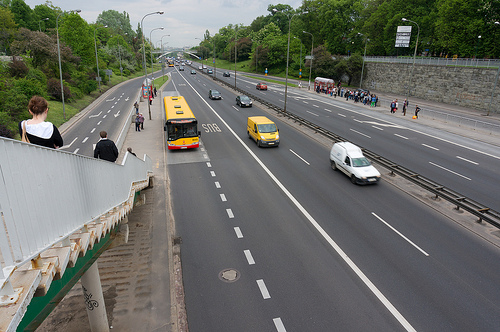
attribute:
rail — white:
[0, 134, 147, 169]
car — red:
[254, 79, 270, 91]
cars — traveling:
[135, 97, 397, 201]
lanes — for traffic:
[155, 80, 410, 319]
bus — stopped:
[158, 89, 202, 154]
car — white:
[315, 136, 382, 192]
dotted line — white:
[202, 173, 291, 330]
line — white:
[169, 60, 419, 330]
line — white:
[365, 207, 426, 255]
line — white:
[285, 143, 309, 170]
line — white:
[293, 88, 498, 163]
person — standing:
[412, 104, 420, 117]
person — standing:
[402, 95, 409, 105]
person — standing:
[400, 101, 407, 116]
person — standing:
[388, 98, 395, 113]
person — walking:
[93, 128, 120, 161]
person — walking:
[23, 96, 60, 145]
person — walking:
[124, 144, 139, 158]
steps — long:
[1, 137, 155, 327]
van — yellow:
[234, 102, 299, 164]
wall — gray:
[361, 59, 499, 114]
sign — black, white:
[392, 17, 436, 63]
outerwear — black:
[93, 133, 119, 160]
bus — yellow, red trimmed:
[163, 87, 200, 155]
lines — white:
[219, 191, 227, 201]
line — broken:
[198, 142, 286, 330]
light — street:
[138, 4, 164, 33]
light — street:
[145, 25, 165, 40]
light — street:
[157, 32, 173, 52]